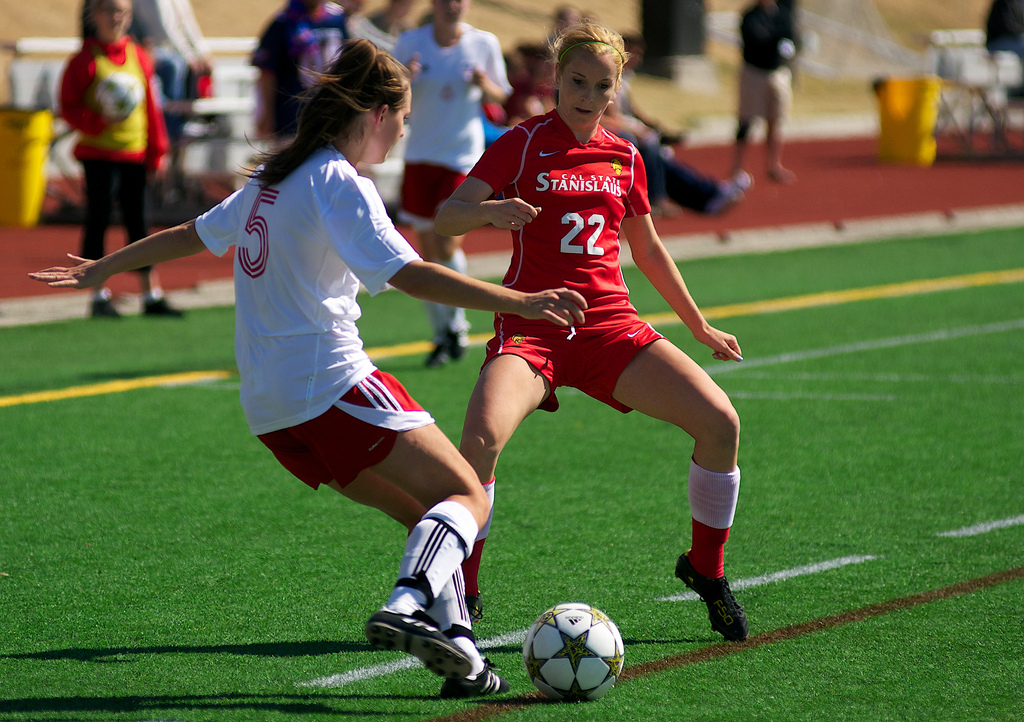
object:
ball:
[495, 559, 661, 712]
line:
[449, 566, 1022, 722]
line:
[305, 510, 1024, 687]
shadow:
[0, 598, 712, 665]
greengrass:
[0, 226, 1024, 722]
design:
[518, 599, 627, 702]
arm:
[425, 117, 534, 269]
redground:
[0, 124, 1024, 297]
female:
[404, 0, 783, 656]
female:
[24, 15, 608, 711]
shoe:
[658, 546, 762, 650]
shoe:
[458, 579, 493, 628]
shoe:
[353, 599, 478, 694]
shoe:
[431, 653, 516, 709]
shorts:
[469, 296, 680, 418]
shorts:
[238, 365, 441, 500]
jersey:
[172, 137, 433, 442]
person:
[17, 0, 204, 333]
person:
[231, 0, 383, 197]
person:
[353, 0, 524, 385]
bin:
[854, 56, 959, 177]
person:
[705, 0, 830, 207]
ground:
[0, 118, 1021, 721]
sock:
[679, 445, 747, 584]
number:
[220, 162, 292, 302]